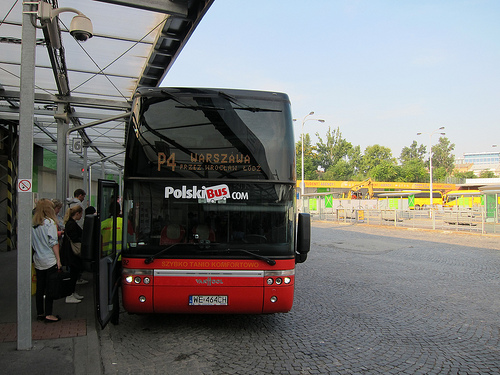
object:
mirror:
[296, 212, 310, 253]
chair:
[336, 208, 382, 225]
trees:
[425, 136, 455, 175]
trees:
[397, 140, 426, 170]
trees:
[313, 126, 353, 173]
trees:
[364, 144, 398, 181]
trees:
[295, 133, 324, 180]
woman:
[59, 205, 83, 304]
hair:
[62, 205, 83, 225]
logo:
[164, 184, 249, 204]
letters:
[231, 191, 248, 200]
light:
[270, 295, 277, 302]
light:
[138, 295, 146, 303]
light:
[284, 277, 291, 284]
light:
[143, 277, 150, 283]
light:
[134, 276, 141, 283]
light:
[416, 127, 445, 136]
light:
[292, 111, 325, 122]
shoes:
[42, 315, 62, 324]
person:
[99, 202, 134, 310]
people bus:
[58, 204, 83, 301]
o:
[173, 189, 183, 199]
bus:
[94, 85, 310, 329]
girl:
[32, 198, 63, 324]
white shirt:
[31, 216, 59, 270]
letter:
[191, 153, 251, 164]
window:
[123, 181, 296, 259]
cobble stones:
[328, 258, 496, 373]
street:
[102, 215, 499, 372]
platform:
[34, 316, 86, 375]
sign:
[72, 137, 83, 153]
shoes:
[36, 315, 45, 322]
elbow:
[50, 242, 59, 248]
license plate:
[188, 294, 227, 305]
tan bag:
[71, 240, 82, 254]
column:
[0, 127, 20, 253]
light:
[69, 15, 93, 43]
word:
[206, 188, 227, 199]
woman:
[30, 197, 62, 324]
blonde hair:
[32, 198, 59, 226]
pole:
[14, 3, 36, 355]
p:
[157, 152, 166, 171]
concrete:
[0, 270, 108, 375]